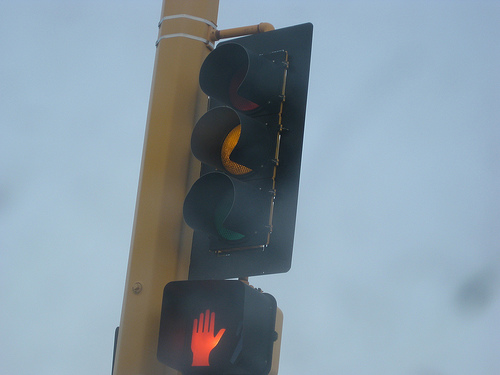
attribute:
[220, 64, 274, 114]
light — red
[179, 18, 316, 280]
frame — black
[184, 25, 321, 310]
sign — green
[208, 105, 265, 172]
sign — yellow